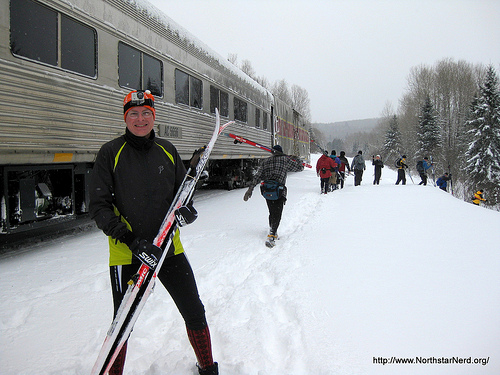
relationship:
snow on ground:
[3, 152, 498, 375] [396, 217, 436, 247]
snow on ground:
[3, 144, 498, 374] [0, 153, 499, 373]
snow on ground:
[3, 152, 498, 375] [12, 247, 495, 372]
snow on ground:
[3, 152, 498, 375] [245, 337, 395, 365]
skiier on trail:
[86, 87, 221, 373] [0, 154, 486, 374]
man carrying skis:
[242, 144, 304, 249] [219, 126, 312, 168]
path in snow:
[124, 173, 328, 373] [3, 144, 498, 374]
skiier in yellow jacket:
[88, 89, 220, 374] [470, 188, 486, 207]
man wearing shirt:
[244, 145, 304, 249] [248, 154, 304, 189]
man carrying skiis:
[244, 145, 304, 249] [227, 129, 313, 167]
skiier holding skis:
[88, 89, 220, 374] [87, 104, 239, 374]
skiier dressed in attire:
[88, 89, 220, 374] [69, 105, 274, 369]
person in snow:
[316, 150, 338, 194] [0, 151, 438, 371]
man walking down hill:
[244, 145, 304, 249] [1, 138, 498, 370]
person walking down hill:
[316, 150, 336, 194] [1, 138, 498, 370]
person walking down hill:
[326, 147, 343, 189] [1, 138, 498, 370]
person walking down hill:
[337, 150, 350, 185] [1, 138, 498, 370]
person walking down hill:
[347, 155, 389, 183] [1, 138, 498, 370]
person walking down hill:
[371, 150, 386, 184] [1, 138, 498, 370]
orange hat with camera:
[123, 90, 155, 115] [130, 87, 150, 106]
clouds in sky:
[153, 0, 499, 124] [303, 10, 401, 104]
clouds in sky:
[332, 65, 367, 103] [187, 7, 484, 121]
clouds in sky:
[153, 0, 499, 124] [224, 22, 451, 132]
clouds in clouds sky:
[153, 0, 499, 124] [150, 0, 500, 125]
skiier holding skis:
[88, 89, 220, 374] [48, 95, 292, 344]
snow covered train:
[3, 152, 498, 375] [150, 9, 322, 184]